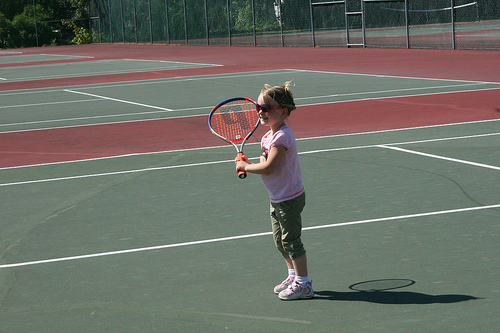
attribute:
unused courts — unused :
[1, 24, 491, 139]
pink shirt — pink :
[258, 123, 307, 220]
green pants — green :
[264, 186, 318, 262]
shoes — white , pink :
[262, 264, 319, 310]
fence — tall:
[77, 5, 498, 52]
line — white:
[0, 201, 500, 269]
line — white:
[377, 144, 498, 174]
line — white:
[0, 129, 500, 186]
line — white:
[59, 85, 173, 111]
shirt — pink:
[256, 126, 307, 205]